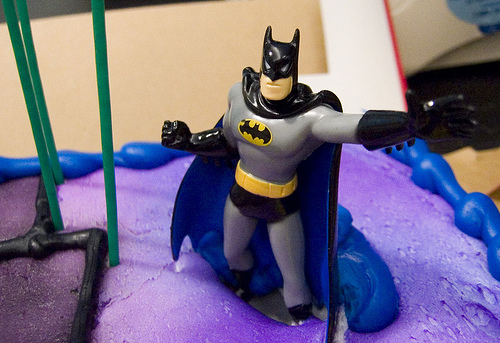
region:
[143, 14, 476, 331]
a batman figure on a cake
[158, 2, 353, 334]
batman is wearing a cape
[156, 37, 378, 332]
the cape is black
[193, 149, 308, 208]
the belt is yellow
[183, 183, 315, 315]
the legs are grey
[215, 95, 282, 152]
batman symbol on the chest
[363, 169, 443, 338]
the icing is purple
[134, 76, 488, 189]
batman is wearing gloves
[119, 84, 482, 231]
the gloves are black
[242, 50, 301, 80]
the eyes are white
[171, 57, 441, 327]
batman figure on cake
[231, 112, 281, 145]
yellow and black logo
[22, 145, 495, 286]
cake has blue edge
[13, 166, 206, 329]
center of cake is purple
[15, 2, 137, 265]
green sticks in cake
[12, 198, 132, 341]
black icing on cake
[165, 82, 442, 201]
left arm is pointing out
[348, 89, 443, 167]
batman wears black glove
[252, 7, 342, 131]
batman wears black mask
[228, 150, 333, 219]
batman wears yellow belt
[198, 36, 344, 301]
This is an action figure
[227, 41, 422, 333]
This is batman, and action figure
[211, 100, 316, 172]
This is a crest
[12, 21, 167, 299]
These are green sticks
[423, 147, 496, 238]
This is a blue boarder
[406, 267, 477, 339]
This is purple frosting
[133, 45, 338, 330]
This is a cake topper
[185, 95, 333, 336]
This is a gray suit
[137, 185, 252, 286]
This is a cape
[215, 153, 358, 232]
This is a belt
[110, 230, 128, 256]
edge of a pipe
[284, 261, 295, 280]
edge of a toy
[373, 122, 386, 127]
edge of an arm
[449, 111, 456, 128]
part of an arm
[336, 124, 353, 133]
part of an hand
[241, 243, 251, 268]
edge of a leg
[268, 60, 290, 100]
face of a toy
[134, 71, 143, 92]
part of a wall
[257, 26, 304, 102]
Batman black face mask.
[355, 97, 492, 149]
Oversized hand with a black glove on it.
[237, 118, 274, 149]
Batman yellow and black logo.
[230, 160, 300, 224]
Batman black and yellow briefs.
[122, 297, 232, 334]
Purple buttercream icing on a cake.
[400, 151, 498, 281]
A bright blue border design.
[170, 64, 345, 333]
Batman's blue and black flying cape.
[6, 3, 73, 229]
Tall green birthday candles.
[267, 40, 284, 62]
Light bouncing off Batman's head.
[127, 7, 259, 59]
A beige painted wall.